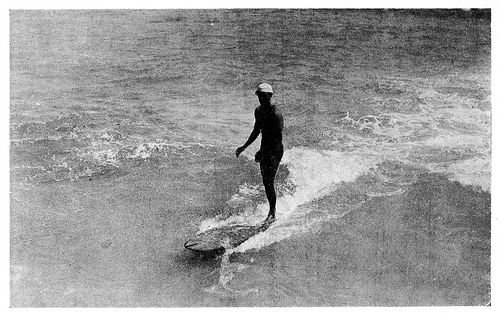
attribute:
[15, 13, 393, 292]
water — wavy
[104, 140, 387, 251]
wave — crashing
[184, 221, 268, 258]
surfboard — old-fashioned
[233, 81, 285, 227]
man — surfing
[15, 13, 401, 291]
waters — shallows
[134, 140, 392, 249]
wave — crashing, splashing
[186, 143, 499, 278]
wave — cresting, crashing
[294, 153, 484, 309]
shape — triangular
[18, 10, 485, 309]
lake — section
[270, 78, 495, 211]
waves — small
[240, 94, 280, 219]
skin — dark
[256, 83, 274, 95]
cap — white 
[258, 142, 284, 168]
shorts — black 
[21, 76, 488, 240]
wave — small 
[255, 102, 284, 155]
top — black 